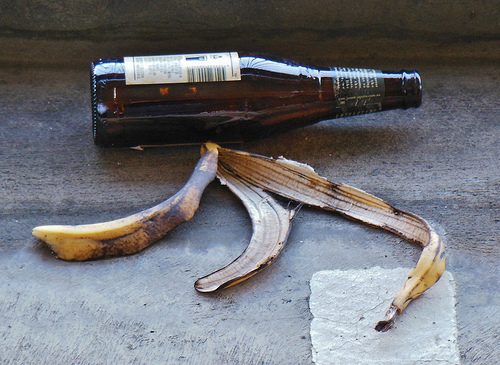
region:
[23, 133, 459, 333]
a peel of banana on the ground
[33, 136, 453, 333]
peel of banana is black and yellow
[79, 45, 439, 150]
a bottle on the floor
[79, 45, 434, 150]
bottle is color brown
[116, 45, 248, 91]
a label on a bottle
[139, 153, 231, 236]
black part of peel of banana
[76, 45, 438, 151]
a bottle of glass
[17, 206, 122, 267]
a yellow part of peel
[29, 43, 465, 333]
banana peel next a banana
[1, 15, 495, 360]
a bottle and a peel on concrete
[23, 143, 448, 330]
A yellow and brown banana peel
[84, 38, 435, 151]
A brown glass bottle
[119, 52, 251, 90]
A white label sticker on a bottle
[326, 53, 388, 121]
A dark green label sticker on a bottle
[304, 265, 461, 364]
A white patch on a surface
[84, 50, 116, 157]
The bottom ridges on a glass bottle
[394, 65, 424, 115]
The ridges on the lip of a bottle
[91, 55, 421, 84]
A reflection of light on top of a glass bottle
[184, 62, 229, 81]
A barcode on a label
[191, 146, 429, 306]
The inside portion of a banana peel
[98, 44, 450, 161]
bottle on the ground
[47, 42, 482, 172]
the glass bottle is brown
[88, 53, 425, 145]
brown glass bottle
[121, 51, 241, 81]
label on glass bottle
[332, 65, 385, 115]
green label on neck of bottle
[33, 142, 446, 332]
yellow banana peel in front of bottle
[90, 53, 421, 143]
bottle behind banana peel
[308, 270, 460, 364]
white square under banana peel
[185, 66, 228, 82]
upc code on label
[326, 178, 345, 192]
black spot on banana peel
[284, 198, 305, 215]
strings on banana peel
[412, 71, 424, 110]
lip of bottle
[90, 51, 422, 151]
an empty beer bottle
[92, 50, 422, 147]
a brown beer bottle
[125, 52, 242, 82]
the label on the side of the beer bottle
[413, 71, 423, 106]
the top of the beer bottle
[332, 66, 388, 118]
a green label on the neck of the beer bottle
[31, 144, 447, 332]
a banana peel on the floor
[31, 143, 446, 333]
a brown and yellow banana peel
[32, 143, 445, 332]
a yellow and brown banana peel and beer bottle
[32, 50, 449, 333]
a banana peel and an empty beer bottle